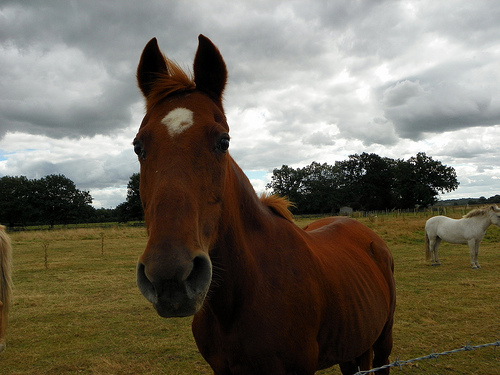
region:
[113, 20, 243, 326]
A horse is looking at the camera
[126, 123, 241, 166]
Horse's eyes are black in color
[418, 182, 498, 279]
A horse in the background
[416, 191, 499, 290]
A side view of a horse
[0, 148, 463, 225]
Tall trees in the background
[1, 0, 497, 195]
The sky is cloudy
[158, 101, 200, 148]
A white spot is on the horse's head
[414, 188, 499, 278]
Horse's coat is cream white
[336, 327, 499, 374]
A fence wire in the foreground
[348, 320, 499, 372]
Fence wire is gray in color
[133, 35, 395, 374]
Brown horse with white spot standing in grass.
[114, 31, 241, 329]
the head of a horse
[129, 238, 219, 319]
the nose on a horse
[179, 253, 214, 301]
the nostril on a horse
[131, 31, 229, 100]
the ears on a horse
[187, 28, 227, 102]
the ear on a horse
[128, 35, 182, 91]
the ear on a horse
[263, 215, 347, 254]
the back of a horse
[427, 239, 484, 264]
the legs of a horse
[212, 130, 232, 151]
the eye of a horse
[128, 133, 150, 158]
the eye of a horse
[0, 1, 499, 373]
attractive photo of at least 1-1/2 horses w/ lowering clouds rolling in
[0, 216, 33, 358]
this is a potential horse, or a potential bale of hay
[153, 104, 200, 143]
cloud shaped star on forehead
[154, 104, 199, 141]
cloud shaped star *could* be photoshopped; red hide is enhanced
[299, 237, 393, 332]
ribsy, here, needs more hay!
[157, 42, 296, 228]
pretty mane, mostly on other side, blowing in the wind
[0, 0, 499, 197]
rain is set to pour forth, clouds be heavy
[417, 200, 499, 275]
mystical looking most-of-a-horse, more attractive if whole head was shown. this is class assignment, probably, however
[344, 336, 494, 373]
a long nasty-looking wire @ top of wire fence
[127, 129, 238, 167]
big, slightly worried eyes